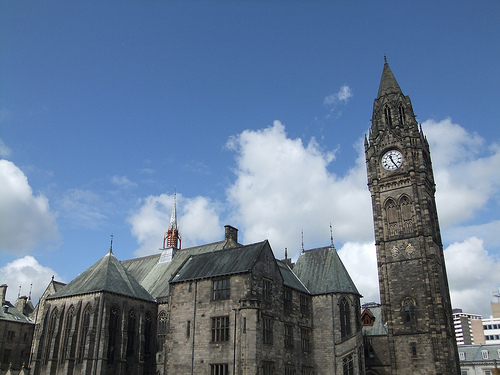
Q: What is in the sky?
A: Clouds.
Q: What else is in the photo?
A: Clock.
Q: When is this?
A: Daytime.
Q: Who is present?
A: Nobody.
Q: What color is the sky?
A: Blue.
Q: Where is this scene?
A: At the church.